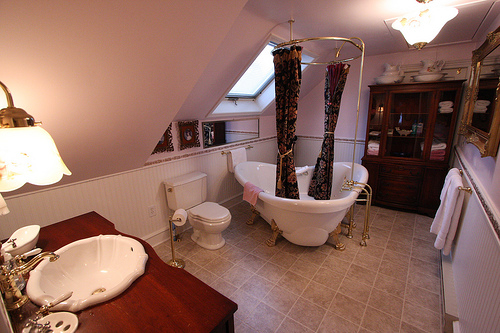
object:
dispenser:
[164, 214, 186, 269]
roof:
[235, 0, 494, 61]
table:
[1, 210, 240, 333]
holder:
[220, 144, 253, 155]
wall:
[0, 138, 278, 248]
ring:
[274, 30, 367, 65]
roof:
[162, 8, 329, 122]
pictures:
[181, 123, 196, 145]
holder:
[168, 220, 175, 263]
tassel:
[271, 41, 302, 53]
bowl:
[409, 72, 450, 83]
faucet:
[0, 237, 74, 333]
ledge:
[143, 135, 279, 167]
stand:
[172, 220, 177, 242]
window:
[222, 41, 275, 98]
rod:
[273, 19, 366, 66]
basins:
[373, 74, 406, 85]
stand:
[176, 226, 182, 243]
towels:
[429, 155, 445, 161]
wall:
[441, 143, 500, 333]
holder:
[169, 211, 181, 221]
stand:
[166, 220, 187, 270]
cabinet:
[356, 78, 466, 219]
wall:
[294, 43, 475, 167]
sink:
[24, 234, 150, 314]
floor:
[152, 200, 444, 332]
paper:
[171, 209, 187, 227]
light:
[389, 0, 460, 53]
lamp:
[0, 79, 74, 194]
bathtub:
[231, 159, 370, 251]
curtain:
[306, 61, 352, 201]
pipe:
[353, 184, 370, 241]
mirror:
[456, 23, 500, 158]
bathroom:
[0, 0, 500, 333]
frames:
[201, 116, 260, 149]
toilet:
[164, 170, 233, 251]